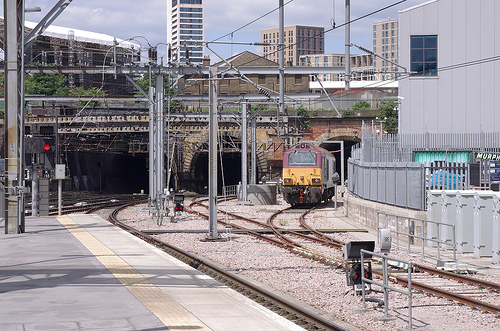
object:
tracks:
[110, 185, 500, 329]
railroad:
[5, 3, 496, 327]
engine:
[282, 147, 338, 206]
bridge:
[18, 106, 399, 190]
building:
[165, 0, 204, 66]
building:
[260, 24, 326, 72]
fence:
[348, 153, 428, 211]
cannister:
[54, 162, 68, 215]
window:
[409, 32, 442, 79]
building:
[395, 1, 499, 149]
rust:
[8, 122, 20, 178]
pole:
[3, 1, 29, 233]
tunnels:
[76, 140, 167, 193]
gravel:
[253, 248, 268, 257]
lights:
[346, 268, 373, 284]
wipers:
[310, 150, 319, 166]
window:
[286, 152, 319, 167]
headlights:
[283, 178, 293, 185]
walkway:
[2, 212, 312, 329]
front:
[281, 141, 322, 205]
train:
[283, 139, 338, 205]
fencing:
[358, 122, 498, 212]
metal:
[346, 119, 499, 212]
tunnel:
[190, 137, 260, 194]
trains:
[280, 137, 344, 204]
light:
[44, 144, 51, 152]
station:
[3, 130, 305, 329]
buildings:
[372, 20, 405, 79]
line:
[56, 212, 216, 330]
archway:
[183, 129, 273, 187]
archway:
[309, 128, 368, 187]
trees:
[23, 72, 69, 95]